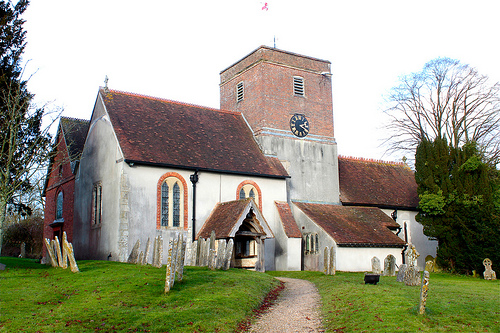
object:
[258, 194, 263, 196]
brick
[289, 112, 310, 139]
clock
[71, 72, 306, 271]
building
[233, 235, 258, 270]
door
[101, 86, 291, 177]
red brick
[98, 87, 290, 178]
roof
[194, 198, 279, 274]
covered entryway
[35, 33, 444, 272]
church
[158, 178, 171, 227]
window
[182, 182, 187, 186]
brick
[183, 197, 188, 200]
brick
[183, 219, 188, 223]
brick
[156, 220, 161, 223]
brick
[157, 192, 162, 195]
brick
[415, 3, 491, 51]
sky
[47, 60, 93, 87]
clouds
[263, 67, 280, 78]
brick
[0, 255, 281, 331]
grass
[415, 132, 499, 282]
tree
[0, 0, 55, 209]
tree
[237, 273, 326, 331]
path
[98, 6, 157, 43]
part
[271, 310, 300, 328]
part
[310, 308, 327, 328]
edge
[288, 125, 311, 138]
part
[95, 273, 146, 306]
part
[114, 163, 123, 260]
edge